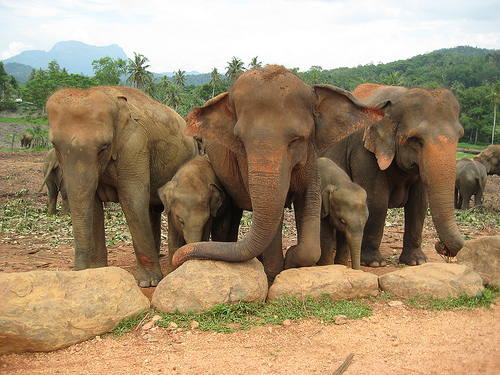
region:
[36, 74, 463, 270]
5 elephants by the blouders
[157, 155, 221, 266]
baby elephant on the left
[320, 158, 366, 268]
baby elephant on the right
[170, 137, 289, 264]
elephant's trunk laying on boulder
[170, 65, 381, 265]
large elephant in the center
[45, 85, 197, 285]
the large elephant on the left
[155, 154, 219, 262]
small baby elephant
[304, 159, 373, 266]
gray baby elephant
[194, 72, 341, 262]
large female elephant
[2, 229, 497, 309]
row of large rocks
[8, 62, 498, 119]
tall green trees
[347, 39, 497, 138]
large grass covered hill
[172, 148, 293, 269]
elephant has long trunk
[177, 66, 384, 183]
elephant has big floppy ears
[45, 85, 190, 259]
gray and brown colored elephant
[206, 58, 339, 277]
gray and brown colored elephant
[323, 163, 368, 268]
gray and brown colored elephant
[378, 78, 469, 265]
gray and brown colored elephant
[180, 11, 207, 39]
white clouds in blue sky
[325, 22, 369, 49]
white clouds in blue sky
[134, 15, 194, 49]
white clouds in blue sky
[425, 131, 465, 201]
the spots are orange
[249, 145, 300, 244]
spots on the nose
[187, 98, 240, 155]
spots on the ear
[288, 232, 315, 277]
the hoof is bent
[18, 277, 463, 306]
the rocks are tan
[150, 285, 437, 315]
grass around the rocks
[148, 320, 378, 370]
the soil is rocky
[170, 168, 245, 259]
the elephant is small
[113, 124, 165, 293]
the leg is long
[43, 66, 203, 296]
an elephant standing outside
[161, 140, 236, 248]
an elephant standing outside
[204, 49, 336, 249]
an elephant standing outside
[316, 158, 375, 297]
an elephant standing outside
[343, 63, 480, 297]
an elephant standing outside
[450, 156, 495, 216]
an elephant standing outside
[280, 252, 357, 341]
a large rock on the ground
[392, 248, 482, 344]
a large rock on the ground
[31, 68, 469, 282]
group of elephants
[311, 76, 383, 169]
middle elephants left ear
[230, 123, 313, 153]
eyes of middle elephant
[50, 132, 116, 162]
eyes of left elephant in front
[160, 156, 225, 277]
baby elephant on left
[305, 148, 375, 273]
baby elephant on right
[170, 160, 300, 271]
center elephant's trunk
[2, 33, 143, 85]
mountain in far distance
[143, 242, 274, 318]
rock elephant rest their trunk on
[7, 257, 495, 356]
rocks in front of the elephants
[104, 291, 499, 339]
grass under the edge of the rocks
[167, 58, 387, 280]
elephant with its trunk on a rock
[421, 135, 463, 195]
orange spot on the elephants trunk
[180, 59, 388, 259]
an elephant with its ears sticking out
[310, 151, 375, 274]
a baby elephant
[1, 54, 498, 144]
a line of trees behind the elephants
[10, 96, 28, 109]
a white building in the distance on the left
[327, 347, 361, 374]
a stick laying in front of the elephants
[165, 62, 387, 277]
an elephant with its leg raised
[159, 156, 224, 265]
a small baby elephant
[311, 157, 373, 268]
a small baby elephant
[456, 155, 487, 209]
a small baby elephant